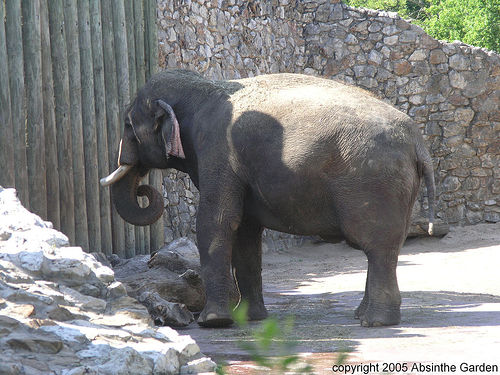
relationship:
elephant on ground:
[98, 69, 438, 327] [159, 230, 498, 374]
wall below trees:
[157, 4, 499, 240] [350, 0, 499, 50]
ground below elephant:
[159, 230, 498, 374] [98, 69, 438, 327]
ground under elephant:
[159, 230, 498, 374] [98, 69, 438, 327]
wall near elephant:
[157, 4, 499, 240] [98, 69, 438, 327]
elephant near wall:
[98, 69, 438, 327] [157, 4, 499, 240]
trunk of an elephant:
[99, 146, 163, 225] [98, 69, 438, 327]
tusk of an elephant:
[98, 162, 130, 186] [98, 69, 438, 327]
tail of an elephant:
[419, 159, 440, 236] [98, 69, 438, 327]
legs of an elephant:
[360, 249, 400, 327] [98, 69, 438, 327]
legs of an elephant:
[355, 271, 368, 320] [98, 69, 438, 327]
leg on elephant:
[187, 201, 256, 336] [94, 53, 446, 354]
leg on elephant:
[178, 196, 248, 333] [68, 50, 472, 300]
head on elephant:
[84, 49, 212, 238] [94, 53, 446, 354]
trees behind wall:
[415, 1, 484, 46] [157, 4, 499, 240]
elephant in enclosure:
[88, 60, 457, 341] [74, 16, 419, 80]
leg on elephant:
[174, 194, 269, 321] [98, 69, 438, 327]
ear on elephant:
[151, 90, 190, 172] [98, 69, 438, 327]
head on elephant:
[104, 74, 203, 232] [98, 69, 438, 327]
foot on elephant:
[348, 283, 410, 340] [98, 69, 438, 327]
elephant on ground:
[98, 69, 438, 327] [187, 289, 499, 374]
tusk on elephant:
[94, 154, 134, 195] [98, 69, 438, 327]